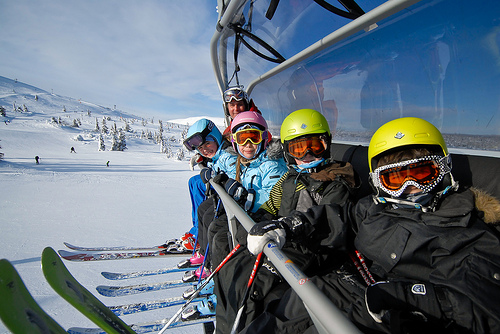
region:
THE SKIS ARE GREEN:
[0, 241, 152, 331]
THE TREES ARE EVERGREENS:
[5, 73, 195, 164]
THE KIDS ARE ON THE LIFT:
[0, 0, 498, 330]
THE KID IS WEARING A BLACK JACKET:
[345, 188, 496, 330]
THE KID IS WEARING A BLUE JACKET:
[222, 148, 293, 211]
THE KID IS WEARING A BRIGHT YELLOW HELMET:
[356, 101, 458, 204]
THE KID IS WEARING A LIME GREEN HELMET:
[275, 105, 355, 175]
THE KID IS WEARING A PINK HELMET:
[228, 105, 269, 157]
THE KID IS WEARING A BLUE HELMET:
[180, 112, 230, 162]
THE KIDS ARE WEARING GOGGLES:
[186, 83, 473, 250]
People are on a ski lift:
[36, 30, 481, 315]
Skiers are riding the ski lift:
[0, 40, 485, 311]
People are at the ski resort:
[0, 42, 490, 323]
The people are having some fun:
[30, 41, 493, 322]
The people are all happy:
[3, 52, 496, 330]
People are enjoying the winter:
[7, 38, 482, 329]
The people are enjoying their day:
[15, 36, 498, 324]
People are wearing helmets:
[36, 50, 497, 293]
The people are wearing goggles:
[10, 36, 485, 327]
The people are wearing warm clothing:
[19, 91, 482, 329]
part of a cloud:
[162, 56, 199, 93]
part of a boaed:
[62, 268, 86, 298]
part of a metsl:
[183, 273, 211, 308]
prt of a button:
[385, 243, 397, 273]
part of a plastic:
[296, 279, 317, 315]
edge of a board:
[44, 257, 71, 310]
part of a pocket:
[391, 200, 413, 250]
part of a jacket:
[421, 243, 439, 288]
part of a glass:
[403, 150, 425, 176]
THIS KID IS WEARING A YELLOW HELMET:
[350, 100, 457, 211]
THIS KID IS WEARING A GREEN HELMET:
[275, 105, 330, 166]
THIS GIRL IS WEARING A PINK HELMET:
[226, 105, 266, 165]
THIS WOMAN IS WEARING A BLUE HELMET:
[175, 112, 230, 157]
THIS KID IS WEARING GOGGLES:
[366, 150, 456, 210]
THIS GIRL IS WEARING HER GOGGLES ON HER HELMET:
[180, 120, 215, 155]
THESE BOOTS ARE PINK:
[175, 242, 212, 278]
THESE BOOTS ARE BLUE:
[180, 271, 231, 321]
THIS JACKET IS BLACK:
[330, 190, 497, 325]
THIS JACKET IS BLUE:
[212, 156, 289, 209]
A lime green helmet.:
[280, 108, 327, 148]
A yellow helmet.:
[365, 114, 450, 179]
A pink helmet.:
[230, 110, 267, 132]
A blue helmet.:
[185, 119, 223, 154]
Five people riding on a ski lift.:
[5, 4, 497, 330]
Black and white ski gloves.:
[247, 215, 441, 331]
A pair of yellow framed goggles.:
[222, 125, 269, 144]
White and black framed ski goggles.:
[352, 156, 450, 199]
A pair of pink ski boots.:
[187, 249, 212, 279]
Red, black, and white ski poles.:
[132, 235, 281, 332]